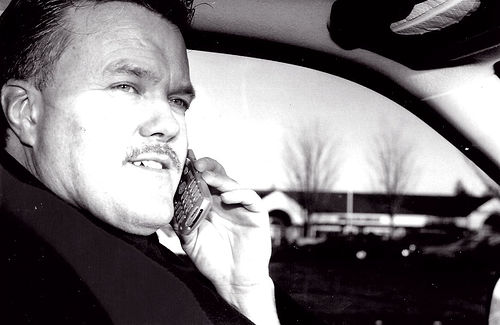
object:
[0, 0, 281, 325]
man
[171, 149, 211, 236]
cellphone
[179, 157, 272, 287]
hand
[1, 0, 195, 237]
head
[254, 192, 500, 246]
shopping mall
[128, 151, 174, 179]
mouth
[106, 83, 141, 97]
eye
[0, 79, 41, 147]
ear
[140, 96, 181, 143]
nose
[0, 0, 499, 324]
car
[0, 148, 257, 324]
jacket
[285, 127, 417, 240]
trees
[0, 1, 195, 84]
hair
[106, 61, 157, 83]
eyebrows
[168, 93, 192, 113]
eyes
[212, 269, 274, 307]
wrist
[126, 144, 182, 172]
moustache